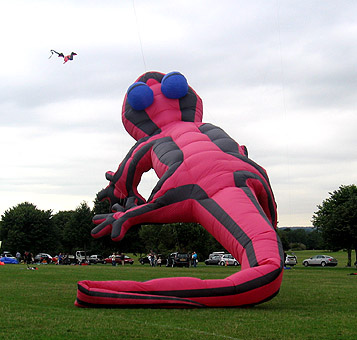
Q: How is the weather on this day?
A: It is cloudy.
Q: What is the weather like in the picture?
A: It is cloudy.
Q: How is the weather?
A: It is cloudy.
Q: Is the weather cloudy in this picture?
A: Yes, it is cloudy.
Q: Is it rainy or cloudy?
A: It is cloudy.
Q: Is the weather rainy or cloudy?
A: It is cloudy.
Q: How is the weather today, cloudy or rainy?
A: It is cloudy.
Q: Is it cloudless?
A: No, it is cloudy.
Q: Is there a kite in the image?
A: Yes, there is a kite.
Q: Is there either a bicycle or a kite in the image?
A: Yes, there is a kite.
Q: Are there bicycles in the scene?
A: No, there are no bicycles.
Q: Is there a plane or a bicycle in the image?
A: No, there are no bicycles or airplanes.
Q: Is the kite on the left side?
A: Yes, the kite is on the left of the image.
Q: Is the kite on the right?
A: No, the kite is on the left of the image.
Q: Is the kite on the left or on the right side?
A: The kite is on the left of the image.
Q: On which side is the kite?
A: The kite is on the left of the image.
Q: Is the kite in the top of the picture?
A: Yes, the kite is in the top of the image.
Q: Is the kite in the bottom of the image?
A: No, the kite is in the top of the image.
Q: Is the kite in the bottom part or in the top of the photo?
A: The kite is in the top of the image.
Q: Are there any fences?
A: No, there are no fences.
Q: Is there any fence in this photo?
A: No, there are no fences.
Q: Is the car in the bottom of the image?
A: Yes, the car is in the bottom of the image.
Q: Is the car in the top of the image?
A: No, the car is in the bottom of the image.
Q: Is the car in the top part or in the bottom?
A: The car is in the bottom of the image.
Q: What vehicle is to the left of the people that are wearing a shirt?
A: The vehicle is a car.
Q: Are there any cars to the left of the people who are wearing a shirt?
A: Yes, there is a car to the left of the people.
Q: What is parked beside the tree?
A: The car is parked beside the tree.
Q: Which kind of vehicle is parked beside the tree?
A: The vehicle is a car.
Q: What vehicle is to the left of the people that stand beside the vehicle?
A: The vehicle is a car.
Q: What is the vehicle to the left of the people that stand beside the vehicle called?
A: The vehicle is a car.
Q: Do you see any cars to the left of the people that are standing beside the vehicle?
A: Yes, there is a car to the left of the people.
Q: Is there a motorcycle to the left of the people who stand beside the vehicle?
A: No, there is a car to the left of the people.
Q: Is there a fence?
A: No, there are no fences.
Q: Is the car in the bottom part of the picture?
A: Yes, the car is in the bottom of the image.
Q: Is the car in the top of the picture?
A: No, the car is in the bottom of the image.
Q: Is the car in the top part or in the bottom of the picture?
A: The car is in the bottom of the image.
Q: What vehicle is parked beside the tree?
A: The vehicle is a car.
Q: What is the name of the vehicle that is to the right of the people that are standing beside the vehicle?
A: The vehicle is a car.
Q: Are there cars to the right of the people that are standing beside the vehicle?
A: Yes, there is a car to the right of the people.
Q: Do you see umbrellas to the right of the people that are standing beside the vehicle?
A: No, there is a car to the right of the people.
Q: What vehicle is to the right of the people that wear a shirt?
A: The vehicle is a car.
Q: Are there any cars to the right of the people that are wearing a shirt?
A: Yes, there is a car to the right of the people.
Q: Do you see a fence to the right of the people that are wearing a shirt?
A: No, there is a car to the right of the people.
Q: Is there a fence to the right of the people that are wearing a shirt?
A: No, there is a car to the right of the people.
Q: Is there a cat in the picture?
A: No, there are no cats.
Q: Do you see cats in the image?
A: No, there are no cats.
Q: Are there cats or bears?
A: No, there are no cats or bears.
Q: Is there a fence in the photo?
A: No, there are no fences.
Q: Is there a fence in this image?
A: No, there are no fences.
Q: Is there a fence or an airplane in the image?
A: No, there are no fences or airplanes.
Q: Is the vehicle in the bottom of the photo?
A: Yes, the vehicle is in the bottom of the image.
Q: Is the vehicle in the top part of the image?
A: No, the vehicle is in the bottom of the image.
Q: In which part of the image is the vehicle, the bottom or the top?
A: The vehicle is in the bottom of the image.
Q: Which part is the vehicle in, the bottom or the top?
A: The vehicle is in the bottom of the image.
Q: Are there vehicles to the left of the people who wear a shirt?
A: Yes, there is a vehicle to the left of the people.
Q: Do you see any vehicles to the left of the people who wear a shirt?
A: Yes, there is a vehicle to the left of the people.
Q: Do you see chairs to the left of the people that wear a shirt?
A: No, there is a vehicle to the left of the people.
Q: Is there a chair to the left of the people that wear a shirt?
A: No, there is a vehicle to the left of the people.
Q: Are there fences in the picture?
A: No, there are no fences.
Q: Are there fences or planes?
A: No, there are no fences or planes.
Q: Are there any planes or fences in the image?
A: No, there are no fences or planes.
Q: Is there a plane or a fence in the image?
A: No, there are no fences or airplanes.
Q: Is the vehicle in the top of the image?
A: No, the vehicle is in the bottom of the image.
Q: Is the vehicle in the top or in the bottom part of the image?
A: The vehicle is in the bottom of the image.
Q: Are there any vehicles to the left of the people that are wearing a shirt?
A: Yes, there is a vehicle to the left of the people.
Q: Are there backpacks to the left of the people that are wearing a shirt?
A: No, there is a vehicle to the left of the people.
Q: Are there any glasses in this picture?
A: No, there are no glasses.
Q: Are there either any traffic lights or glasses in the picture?
A: No, there are no glasses or traffic lights.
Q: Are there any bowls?
A: No, there are no bowls.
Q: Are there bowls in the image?
A: No, there are no bowls.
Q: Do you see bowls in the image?
A: No, there are no bowls.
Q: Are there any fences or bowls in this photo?
A: No, there are no bowls or fences.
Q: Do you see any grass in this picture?
A: Yes, there is grass.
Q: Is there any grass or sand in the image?
A: Yes, there is grass.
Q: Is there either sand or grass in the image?
A: Yes, there is grass.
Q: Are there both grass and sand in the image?
A: No, there is grass but no sand.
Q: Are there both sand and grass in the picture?
A: No, there is grass but no sand.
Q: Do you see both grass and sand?
A: No, there is grass but no sand.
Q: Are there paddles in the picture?
A: No, there are no paddles.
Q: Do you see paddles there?
A: No, there are no paddles.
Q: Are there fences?
A: No, there are no fences.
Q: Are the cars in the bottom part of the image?
A: Yes, the cars are in the bottom of the image.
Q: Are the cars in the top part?
A: No, the cars are in the bottom of the image.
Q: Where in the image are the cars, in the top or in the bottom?
A: The cars are in the bottom of the image.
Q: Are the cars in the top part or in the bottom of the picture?
A: The cars are in the bottom of the image.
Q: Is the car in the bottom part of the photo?
A: Yes, the car is in the bottom of the image.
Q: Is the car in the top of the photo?
A: No, the car is in the bottom of the image.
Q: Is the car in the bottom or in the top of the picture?
A: The car is in the bottom of the image.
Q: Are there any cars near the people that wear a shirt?
A: Yes, there is a car near the people.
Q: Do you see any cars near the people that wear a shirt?
A: Yes, there is a car near the people.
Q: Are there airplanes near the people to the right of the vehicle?
A: No, there is a car near the people.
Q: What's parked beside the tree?
A: The car is parked beside the tree.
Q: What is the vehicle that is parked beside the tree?
A: The vehicle is a car.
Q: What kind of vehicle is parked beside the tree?
A: The vehicle is a car.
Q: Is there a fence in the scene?
A: No, there are no fences.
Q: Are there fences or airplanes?
A: No, there are no fences or airplanes.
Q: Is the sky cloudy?
A: Yes, the sky is cloudy.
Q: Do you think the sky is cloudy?
A: Yes, the sky is cloudy.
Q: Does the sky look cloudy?
A: Yes, the sky is cloudy.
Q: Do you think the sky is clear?
A: No, the sky is cloudy.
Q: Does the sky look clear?
A: No, the sky is cloudy.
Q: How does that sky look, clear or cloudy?
A: The sky is cloudy.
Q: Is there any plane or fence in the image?
A: No, there are no fences or airplanes.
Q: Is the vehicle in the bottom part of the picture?
A: Yes, the vehicle is in the bottom of the image.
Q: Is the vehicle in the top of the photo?
A: No, the vehicle is in the bottom of the image.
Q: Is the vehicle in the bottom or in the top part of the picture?
A: The vehicle is in the bottom of the image.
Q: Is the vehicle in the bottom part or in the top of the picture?
A: The vehicle is in the bottom of the image.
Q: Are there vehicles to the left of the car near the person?
A: Yes, there is a vehicle to the left of the car.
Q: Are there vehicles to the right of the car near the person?
A: No, the vehicle is to the left of the car.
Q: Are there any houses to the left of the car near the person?
A: No, there is a vehicle to the left of the car.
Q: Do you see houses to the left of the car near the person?
A: No, there is a vehicle to the left of the car.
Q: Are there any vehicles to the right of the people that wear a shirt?
A: Yes, there is a vehicle to the right of the people.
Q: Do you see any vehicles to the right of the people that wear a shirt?
A: Yes, there is a vehicle to the right of the people.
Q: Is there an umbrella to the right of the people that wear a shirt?
A: No, there is a vehicle to the right of the people.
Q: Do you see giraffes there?
A: No, there are no giraffes.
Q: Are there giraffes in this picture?
A: No, there are no giraffes.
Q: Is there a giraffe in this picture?
A: No, there are no giraffes.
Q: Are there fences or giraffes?
A: No, there are no giraffes or fences.